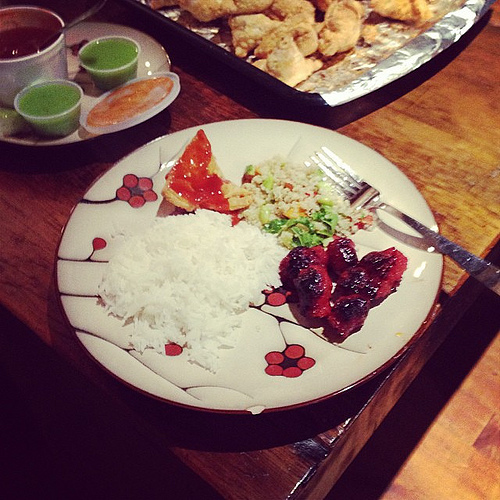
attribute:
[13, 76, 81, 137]
container — plastic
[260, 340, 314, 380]
flower — red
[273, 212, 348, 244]
lettuce — green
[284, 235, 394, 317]
meat — some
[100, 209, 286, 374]
rice — white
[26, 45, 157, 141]
plate — small, round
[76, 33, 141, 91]
container — plastic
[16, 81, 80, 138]
sauce — green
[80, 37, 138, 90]
sauce — green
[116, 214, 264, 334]
rice — white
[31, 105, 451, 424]
plate — round, ceramic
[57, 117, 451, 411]
plate — white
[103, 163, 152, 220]
rose design — red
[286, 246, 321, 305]
glaze — burnt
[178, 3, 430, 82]
wontons — fried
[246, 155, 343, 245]
vegetables — some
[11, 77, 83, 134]
greensauce — green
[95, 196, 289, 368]
rice — white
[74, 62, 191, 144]
top — container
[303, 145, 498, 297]
fork — metal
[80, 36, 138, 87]
cup — small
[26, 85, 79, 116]
liquid — green